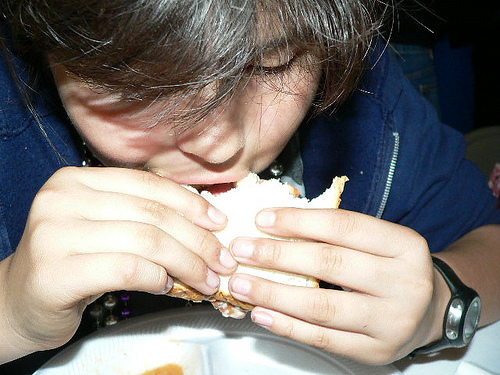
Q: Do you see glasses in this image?
A: No, there are no glasses.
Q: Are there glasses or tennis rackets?
A: No, there are no glasses or tennis rackets.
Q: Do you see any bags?
A: No, there are no bags.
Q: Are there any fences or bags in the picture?
A: No, there are no bags or fences.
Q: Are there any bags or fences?
A: No, there are no bags or fences.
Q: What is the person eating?
A: The person is eating a bread.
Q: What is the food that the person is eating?
A: The food is a bread.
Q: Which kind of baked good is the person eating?
A: The person is eating a bread.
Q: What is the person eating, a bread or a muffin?
A: The person is eating a bread.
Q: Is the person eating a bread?
A: Yes, the person is eating a bread.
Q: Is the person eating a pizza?
A: No, the person is eating a bread.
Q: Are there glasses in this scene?
A: No, there are no glasses.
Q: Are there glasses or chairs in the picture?
A: No, there are no glasses or chairs.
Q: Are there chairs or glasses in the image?
A: No, there are no glasses or chairs.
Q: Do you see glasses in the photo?
A: No, there are no glasses.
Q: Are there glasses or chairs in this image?
A: No, there are no glasses or chairs.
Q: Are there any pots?
A: No, there are no pots.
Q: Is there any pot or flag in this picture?
A: No, there are no pots or flags.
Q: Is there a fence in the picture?
A: No, there are no fences.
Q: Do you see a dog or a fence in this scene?
A: No, there are no fences or dogs.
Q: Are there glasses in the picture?
A: No, there are no glasses.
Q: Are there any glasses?
A: No, there are no glasses.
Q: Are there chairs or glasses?
A: No, there are no glasses or chairs.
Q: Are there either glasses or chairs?
A: No, there are no glasses or chairs.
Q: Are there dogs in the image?
A: No, there are no dogs.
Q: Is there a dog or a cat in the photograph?
A: No, there are no dogs or cats.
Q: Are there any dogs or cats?
A: No, there are no dogs or cats.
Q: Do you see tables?
A: Yes, there is a table.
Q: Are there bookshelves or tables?
A: Yes, there is a table.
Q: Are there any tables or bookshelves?
A: Yes, there is a table.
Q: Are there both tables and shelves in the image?
A: No, there is a table but no shelves.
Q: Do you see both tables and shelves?
A: No, there is a table but no shelves.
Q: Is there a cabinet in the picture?
A: No, there are no cabinets.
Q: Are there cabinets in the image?
A: No, there are no cabinets.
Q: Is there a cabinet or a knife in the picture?
A: No, there are no cabinets or knives.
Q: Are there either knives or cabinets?
A: No, there are no cabinets or knives.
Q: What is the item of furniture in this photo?
A: The piece of furniture is a table.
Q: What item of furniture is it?
A: The piece of furniture is a table.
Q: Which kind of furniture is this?
A: This is a table.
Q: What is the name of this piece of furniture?
A: This is a table.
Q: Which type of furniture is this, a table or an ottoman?
A: This is a table.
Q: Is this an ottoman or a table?
A: This is a table.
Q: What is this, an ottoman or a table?
A: This is a table.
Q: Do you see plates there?
A: Yes, there is a plate.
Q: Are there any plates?
A: Yes, there is a plate.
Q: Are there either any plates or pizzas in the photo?
A: Yes, there is a plate.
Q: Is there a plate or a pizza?
A: Yes, there is a plate.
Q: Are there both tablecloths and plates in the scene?
A: No, there is a plate but no tablecloths.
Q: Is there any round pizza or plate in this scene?
A: Yes, there is a round plate.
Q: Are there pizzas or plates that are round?
A: Yes, the plate is round.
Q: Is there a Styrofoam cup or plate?
A: Yes, there is a Styrofoam plate.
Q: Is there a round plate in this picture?
A: Yes, there is a round plate.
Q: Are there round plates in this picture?
A: Yes, there is a round plate.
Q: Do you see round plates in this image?
A: Yes, there is a round plate.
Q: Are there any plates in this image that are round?
A: Yes, there is a plate that is round.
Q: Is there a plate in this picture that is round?
A: Yes, there is a plate that is round.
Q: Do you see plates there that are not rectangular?
A: Yes, there is a round plate.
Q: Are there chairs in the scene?
A: No, there are no chairs.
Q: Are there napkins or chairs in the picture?
A: No, there are no chairs or napkins.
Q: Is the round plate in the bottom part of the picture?
A: Yes, the plate is in the bottom of the image.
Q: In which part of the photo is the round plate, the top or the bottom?
A: The plate is in the bottom of the image.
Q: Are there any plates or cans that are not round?
A: No, there is a plate but it is round.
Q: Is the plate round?
A: Yes, the plate is round.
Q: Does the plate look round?
A: Yes, the plate is round.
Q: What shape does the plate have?
A: The plate has round shape.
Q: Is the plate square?
A: No, the plate is round.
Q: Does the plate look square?
A: No, the plate is round.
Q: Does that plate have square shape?
A: No, the plate is round.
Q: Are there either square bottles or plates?
A: No, there is a plate but it is round.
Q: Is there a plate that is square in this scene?
A: No, there is a plate but it is round.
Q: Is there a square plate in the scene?
A: No, there is a plate but it is round.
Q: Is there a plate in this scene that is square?
A: No, there is a plate but it is round.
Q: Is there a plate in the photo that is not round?
A: No, there is a plate but it is round.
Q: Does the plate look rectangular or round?
A: The plate is round.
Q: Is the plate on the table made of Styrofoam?
A: Yes, the plate is made of styrofoam.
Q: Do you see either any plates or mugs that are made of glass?
A: No, there is a plate but it is made of styrofoam.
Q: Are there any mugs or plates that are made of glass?
A: No, there is a plate but it is made of styrofoam.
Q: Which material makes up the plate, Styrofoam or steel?
A: The plate is made of styrofoam.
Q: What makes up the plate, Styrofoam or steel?
A: The plate is made of styrofoam.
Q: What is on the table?
A: The plate is on the table.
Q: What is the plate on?
A: The plate is on the table.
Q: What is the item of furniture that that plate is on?
A: The piece of furniture is a table.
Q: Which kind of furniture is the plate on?
A: The plate is on the table.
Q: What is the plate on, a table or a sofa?
A: The plate is on a table.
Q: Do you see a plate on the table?
A: Yes, there is a plate on the table.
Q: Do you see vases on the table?
A: No, there is a plate on the table.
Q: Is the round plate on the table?
A: Yes, the plate is on the table.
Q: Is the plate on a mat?
A: No, the plate is on the table.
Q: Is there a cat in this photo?
A: No, there are no cats.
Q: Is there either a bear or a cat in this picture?
A: No, there are no cats or bears.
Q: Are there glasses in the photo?
A: No, there are no glasses.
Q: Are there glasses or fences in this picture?
A: No, there are no glasses or fences.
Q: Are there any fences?
A: No, there are no fences.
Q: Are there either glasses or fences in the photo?
A: No, there are no fences or glasses.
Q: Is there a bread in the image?
A: Yes, there is a bread.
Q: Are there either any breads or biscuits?
A: Yes, there is a bread.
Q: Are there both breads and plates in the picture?
A: Yes, there are both a bread and a plate.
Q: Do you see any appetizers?
A: No, there are no appetizers.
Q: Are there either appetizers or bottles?
A: No, there are no appetizers or bottles.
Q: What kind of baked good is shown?
A: The baked good is a bread.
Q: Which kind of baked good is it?
A: The food is a bread.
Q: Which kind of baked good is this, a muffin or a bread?
A: That is a bread.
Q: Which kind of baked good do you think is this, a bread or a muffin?
A: That is a bread.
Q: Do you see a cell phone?
A: No, there are no cell phones.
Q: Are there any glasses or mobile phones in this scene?
A: No, there are no mobile phones or glasses.